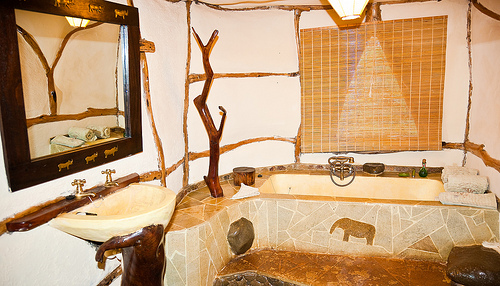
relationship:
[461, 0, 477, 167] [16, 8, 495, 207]
crack in wall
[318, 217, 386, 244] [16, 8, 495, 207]
elephant designed on wall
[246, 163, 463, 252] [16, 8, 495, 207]
bath tub in bathroom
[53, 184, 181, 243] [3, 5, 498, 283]
sink in bathroom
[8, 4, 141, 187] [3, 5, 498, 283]
mirror in bathroom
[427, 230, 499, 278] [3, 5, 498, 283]
sitting area in bathroom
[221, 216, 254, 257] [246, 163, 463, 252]
rock on side of bath tub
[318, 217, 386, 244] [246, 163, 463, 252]
elephant on bath tub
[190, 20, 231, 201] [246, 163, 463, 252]
tree branch on bath tub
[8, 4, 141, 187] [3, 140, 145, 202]
mirror has wooden frame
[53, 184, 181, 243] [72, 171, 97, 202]
sink has faucet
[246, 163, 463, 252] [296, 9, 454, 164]
bath tub near bamboo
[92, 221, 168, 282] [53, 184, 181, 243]
wood under sink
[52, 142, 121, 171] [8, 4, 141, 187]
animals are under mirror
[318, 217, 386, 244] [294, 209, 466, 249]
elephant in tile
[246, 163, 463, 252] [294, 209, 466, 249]
bath tub surrounded by tile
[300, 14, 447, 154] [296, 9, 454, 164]
bamboo made of bamboo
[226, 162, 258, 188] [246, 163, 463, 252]
wooden box on bath tub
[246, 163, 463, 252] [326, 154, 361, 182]
bath tub has faucet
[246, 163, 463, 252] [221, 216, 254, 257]
bath tub rimmed with rock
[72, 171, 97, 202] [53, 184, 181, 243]
faucet from sink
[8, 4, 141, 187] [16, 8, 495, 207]
mirror on wall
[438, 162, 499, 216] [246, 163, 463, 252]
towels are at side of bath tub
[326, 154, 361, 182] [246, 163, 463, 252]
faucet on bath tub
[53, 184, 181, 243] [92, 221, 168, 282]
sink on wood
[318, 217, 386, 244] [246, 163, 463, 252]
elephant on side of bath tub